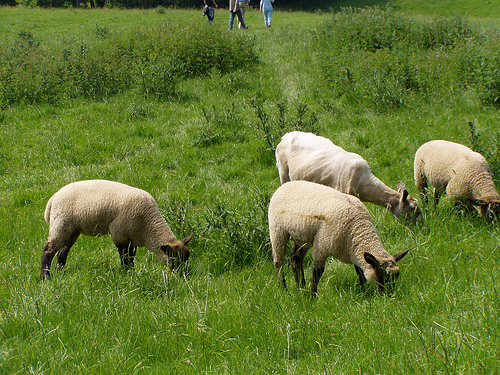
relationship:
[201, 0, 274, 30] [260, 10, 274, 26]
people wearing jeans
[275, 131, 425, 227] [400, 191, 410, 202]
sheep has ear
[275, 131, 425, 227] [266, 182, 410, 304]
sheep by sheep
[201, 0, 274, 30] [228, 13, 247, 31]
people wearing jeans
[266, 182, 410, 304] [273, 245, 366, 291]
sheep has legs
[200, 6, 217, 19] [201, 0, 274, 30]
jacket on people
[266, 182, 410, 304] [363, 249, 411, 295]
sheep has head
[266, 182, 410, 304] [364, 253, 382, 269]
sheep has ear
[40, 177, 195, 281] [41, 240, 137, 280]
sheep has legs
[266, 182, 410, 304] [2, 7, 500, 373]
sheep in field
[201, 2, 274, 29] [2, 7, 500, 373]
people are in field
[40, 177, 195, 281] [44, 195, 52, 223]
sheep has tail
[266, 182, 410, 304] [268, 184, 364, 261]
sheep has body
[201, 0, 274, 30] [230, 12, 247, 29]
people has legs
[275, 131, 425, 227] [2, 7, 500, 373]
sheep in field